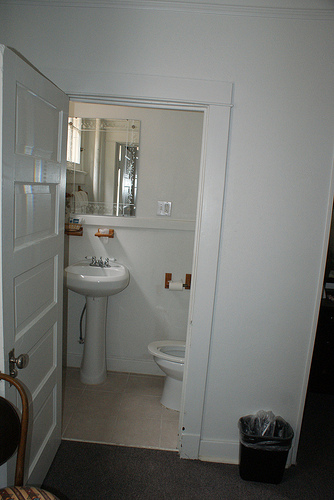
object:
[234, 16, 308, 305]
wall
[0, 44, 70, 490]
bathroom door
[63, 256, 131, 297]
sink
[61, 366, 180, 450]
floor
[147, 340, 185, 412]
toilet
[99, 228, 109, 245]
cups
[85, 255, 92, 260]
knob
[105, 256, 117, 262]
knob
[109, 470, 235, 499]
ground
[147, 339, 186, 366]
toilet seat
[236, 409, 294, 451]
bag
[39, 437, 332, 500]
floor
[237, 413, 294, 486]
basket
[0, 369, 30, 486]
back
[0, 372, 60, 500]
chair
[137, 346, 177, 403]
towel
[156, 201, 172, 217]
outlet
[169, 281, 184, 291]
paper roll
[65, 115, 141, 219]
mirror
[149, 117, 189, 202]
wall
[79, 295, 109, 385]
stand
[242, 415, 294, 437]
liner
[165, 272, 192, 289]
rack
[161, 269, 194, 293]
dispenser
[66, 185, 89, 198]
towel rack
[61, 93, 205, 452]
bathroom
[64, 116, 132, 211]
reflection